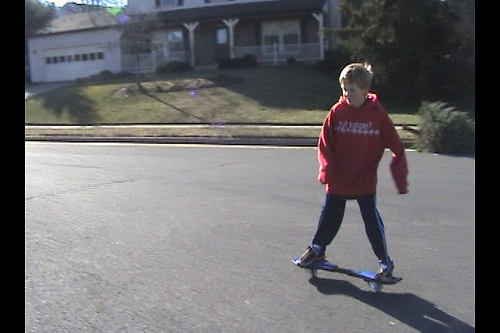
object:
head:
[340, 62, 373, 105]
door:
[216, 28, 235, 59]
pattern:
[336, 120, 371, 129]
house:
[120, 0, 343, 71]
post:
[318, 15, 324, 56]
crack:
[27, 176, 140, 202]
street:
[24, 140, 474, 332]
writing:
[333, 120, 378, 133]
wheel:
[373, 287, 381, 295]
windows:
[97, 51, 105, 60]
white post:
[228, 17, 235, 60]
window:
[265, 33, 281, 53]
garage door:
[43, 47, 73, 83]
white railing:
[234, 45, 276, 63]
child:
[297, 61, 409, 279]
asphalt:
[23, 140, 475, 332]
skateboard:
[292, 255, 403, 293]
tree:
[410, 101, 475, 153]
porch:
[129, 15, 321, 66]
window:
[167, 37, 184, 52]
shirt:
[316, 93, 409, 196]